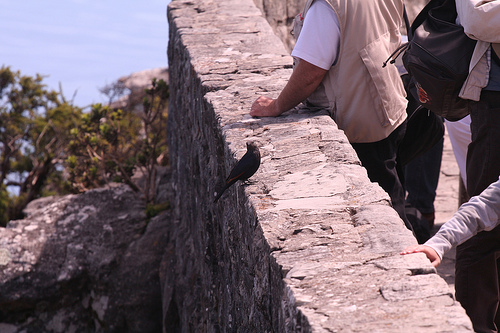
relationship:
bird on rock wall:
[213, 138, 260, 198] [166, 1, 476, 331]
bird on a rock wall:
[213, 138, 260, 198] [161, 2, 498, 332]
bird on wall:
[213, 138, 260, 198] [161, 2, 498, 332]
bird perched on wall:
[213, 138, 260, 198] [161, 2, 498, 332]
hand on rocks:
[397, 235, 443, 270] [369, 252, 436, 272]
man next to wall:
[249, 1, 418, 147] [161, 2, 498, 332]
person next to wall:
[399, 175, 499, 266] [161, 2, 498, 332]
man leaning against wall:
[249, 1, 418, 147] [165, 36, 302, 324]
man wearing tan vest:
[249, 1, 418, 147] [324, 11, 411, 142]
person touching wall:
[399, 175, 499, 266] [382, 221, 445, 281]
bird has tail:
[213, 138, 260, 198] [210, 177, 234, 204]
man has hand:
[249, 1, 418, 147] [240, 71, 304, 123]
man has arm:
[249, 1, 418, 147] [250, 6, 342, 118]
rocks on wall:
[369, 252, 436, 272] [165, 9, 385, 330]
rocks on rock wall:
[153, 25, 303, 332] [166, 1, 476, 331]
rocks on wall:
[369, 252, 436, 272] [161, 2, 498, 332]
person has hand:
[399, 175, 499, 266] [399, 240, 442, 267]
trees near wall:
[0, 60, 168, 225] [161, 2, 498, 332]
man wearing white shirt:
[249, 1, 416, 242] [290, 3, 337, 73]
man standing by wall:
[249, 1, 418, 147] [161, 2, 498, 332]